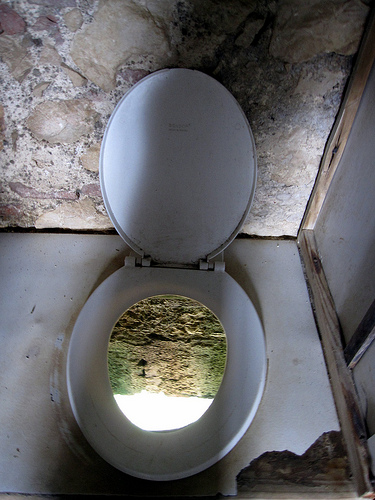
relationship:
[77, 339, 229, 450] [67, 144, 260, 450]
seat attached to toilet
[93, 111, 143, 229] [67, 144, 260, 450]
reflection on toilet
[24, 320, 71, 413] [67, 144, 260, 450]
surface around toilet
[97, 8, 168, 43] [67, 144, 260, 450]
wall behind toilet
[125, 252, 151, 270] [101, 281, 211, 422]
hinge attached to cover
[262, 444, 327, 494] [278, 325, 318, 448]
crack on floor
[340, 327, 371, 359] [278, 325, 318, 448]
plank on floor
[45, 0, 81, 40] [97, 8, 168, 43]
rock on wall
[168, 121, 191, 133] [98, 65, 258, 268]
name are on cover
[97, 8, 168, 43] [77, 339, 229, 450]
wall under seat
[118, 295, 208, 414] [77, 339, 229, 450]
area under seat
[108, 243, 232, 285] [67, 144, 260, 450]
step on toilet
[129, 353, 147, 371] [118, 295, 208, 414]
knot on plant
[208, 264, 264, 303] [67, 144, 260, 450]
edge of toilet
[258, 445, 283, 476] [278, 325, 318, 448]
wood on floor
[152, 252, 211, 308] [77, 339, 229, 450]
hinge of seat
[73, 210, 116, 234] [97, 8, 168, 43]
stone on wall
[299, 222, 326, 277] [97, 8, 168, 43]
frame attached to wall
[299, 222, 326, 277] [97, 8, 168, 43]
frame on wall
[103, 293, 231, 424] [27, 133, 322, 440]
portal on bathroom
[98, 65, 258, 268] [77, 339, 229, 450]
cover attached to seat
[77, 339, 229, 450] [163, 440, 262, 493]
seat fitted on board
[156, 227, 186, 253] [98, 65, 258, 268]
dirt on cover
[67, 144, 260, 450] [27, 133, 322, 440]
toilet inside bathroom